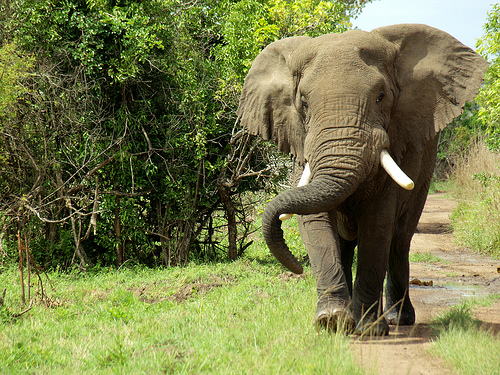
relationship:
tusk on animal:
[380, 150, 415, 193] [235, 23, 490, 334]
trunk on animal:
[262, 125, 388, 273] [235, 23, 490, 334]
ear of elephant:
[234, 35, 304, 167] [208, 17, 485, 353]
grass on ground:
[1, 268, 341, 373] [1, 265, 358, 373]